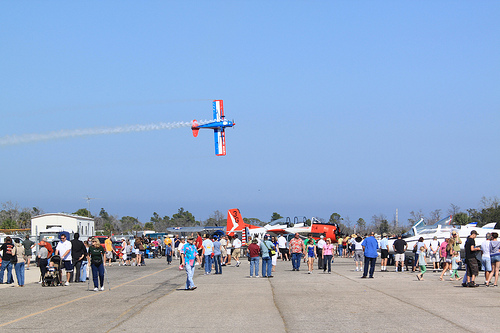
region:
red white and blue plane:
[167, 88, 236, 190]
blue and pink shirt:
[153, 235, 210, 328]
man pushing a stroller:
[25, 233, 72, 298]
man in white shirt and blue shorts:
[56, 228, 80, 295]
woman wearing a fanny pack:
[85, 239, 115, 319]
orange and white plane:
[175, 205, 348, 264]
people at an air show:
[0, 194, 460, 321]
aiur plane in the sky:
[157, 95, 290, 174]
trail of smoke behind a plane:
[37, 102, 207, 163]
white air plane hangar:
[31, 204, 112, 236]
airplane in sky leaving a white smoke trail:
[5, 91, 247, 163]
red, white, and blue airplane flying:
[189, 94, 240, 158]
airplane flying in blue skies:
[0, 5, 496, 201]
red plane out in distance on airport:
[207, 206, 345, 237]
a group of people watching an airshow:
[1, 67, 497, 287]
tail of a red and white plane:
[219, 201, 246, 245]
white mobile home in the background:
[29, 210, 106, 244]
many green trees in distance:
[8, 197, 248, 223]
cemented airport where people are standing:
[11, 251, 489, 329]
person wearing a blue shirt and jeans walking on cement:
[151, 235, 207, 292]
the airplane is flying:
[46, 81, 273, 204]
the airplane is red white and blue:
[117, 75, 261, 181]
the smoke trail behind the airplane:
[23, 115, 217, 135]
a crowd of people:
[87, 228, 485, 283]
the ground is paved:
[169, 285, 461, 331]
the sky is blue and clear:
[249, 7, 445, 68]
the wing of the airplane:
[210, 127, 227, 158]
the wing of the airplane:
[208, 94, 227, 119]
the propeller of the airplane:
[229, 117, 241, 133]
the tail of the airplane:
[181, 110, 201, 144]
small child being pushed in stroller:
[35, 254, 67, 285]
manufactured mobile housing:
[27, 214, 106, 235]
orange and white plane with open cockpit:
[222, 206, 342, 239]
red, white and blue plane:
[185, 97, 239, 157]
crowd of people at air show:
[143, 228, 495, 283]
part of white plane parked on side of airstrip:
[378, 214, 497, 246]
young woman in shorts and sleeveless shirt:
[302, 236, 321, 276]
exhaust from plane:
[7, 112, 193, 146]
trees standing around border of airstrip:
[88, 208, 194, 228]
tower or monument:
[386, 202, 406, 228]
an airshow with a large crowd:
[3, 65, 499, 295]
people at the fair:
[5, 187, 499, 292]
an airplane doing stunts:
[138, 84, 284, 182]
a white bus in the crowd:
[5, 196, 120, 309]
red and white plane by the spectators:
[206, 194, 353, 261]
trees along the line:
[3, 192, 494, 236]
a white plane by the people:
[353, 210, 499, 260]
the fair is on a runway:
[34, 227, 476, 317]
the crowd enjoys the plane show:
[77, 191, 495, 266]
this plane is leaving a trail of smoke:
[7, 87, 186, 190]